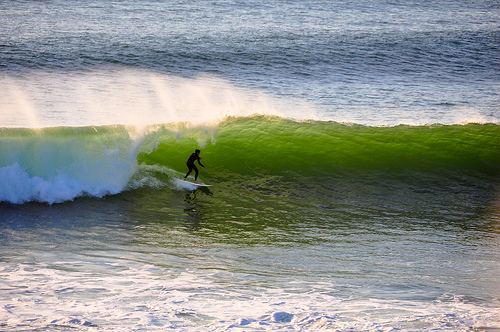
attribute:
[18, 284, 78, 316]
ripples — small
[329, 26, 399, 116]
wave — small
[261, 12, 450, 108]
water — splashing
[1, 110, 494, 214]
wave — small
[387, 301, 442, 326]
wave — small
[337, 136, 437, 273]
water — sudsy , white 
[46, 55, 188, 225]
wave — small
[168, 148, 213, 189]
wetsuit — long sleeved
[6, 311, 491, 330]
shoreline — well-churned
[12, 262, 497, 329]
ripples — small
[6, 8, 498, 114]
ocean — blue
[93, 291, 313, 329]
ripples — small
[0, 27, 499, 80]
wave — small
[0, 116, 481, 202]
wave — small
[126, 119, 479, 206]
wave — bottle-green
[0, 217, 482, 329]
waves — white tipped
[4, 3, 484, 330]
water — blue, bright green, glowing, wavy